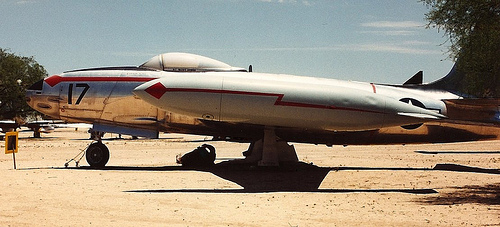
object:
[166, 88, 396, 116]
red stripes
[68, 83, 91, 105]
17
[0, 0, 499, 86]
sky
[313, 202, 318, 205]
rock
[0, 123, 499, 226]
ground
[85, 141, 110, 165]
wheel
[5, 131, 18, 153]
sign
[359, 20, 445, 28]
cloud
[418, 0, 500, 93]
vegetation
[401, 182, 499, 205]
shadow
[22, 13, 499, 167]
airplane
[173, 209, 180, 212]
rock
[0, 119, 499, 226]
sand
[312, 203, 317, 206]
rock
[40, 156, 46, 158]
rock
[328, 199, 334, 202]
rock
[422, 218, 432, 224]
rock